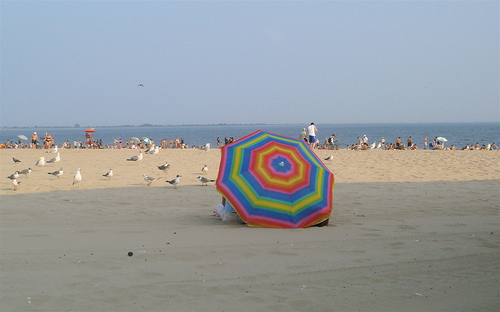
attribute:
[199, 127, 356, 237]
umbrella — large, rainbow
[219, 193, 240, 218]
shirt — blue , black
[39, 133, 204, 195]
birds — black, grey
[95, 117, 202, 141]
island — distant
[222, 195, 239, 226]
person — under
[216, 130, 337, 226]
umbrella — blue, yellow, rainbow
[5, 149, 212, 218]
seagulls — grey, white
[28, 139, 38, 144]
trunks — black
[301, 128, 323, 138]
shirt — white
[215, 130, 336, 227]
colored umbrellas — different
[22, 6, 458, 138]
sky — hazy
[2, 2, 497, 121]
sky — grey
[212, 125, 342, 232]
umbrella — large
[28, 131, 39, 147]
man — shirtless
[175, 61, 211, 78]
ground — sunny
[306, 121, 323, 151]
top — white